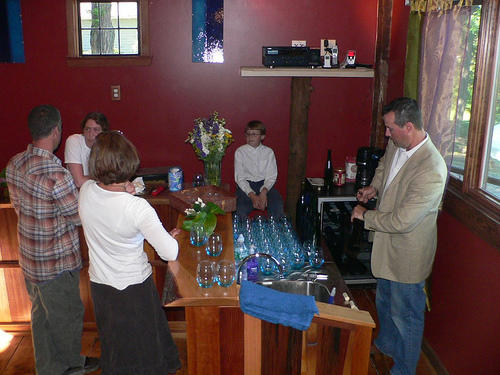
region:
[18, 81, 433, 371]
five people in red room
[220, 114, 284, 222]
boy sitting against wolf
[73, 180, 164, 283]
white shirt of woman standing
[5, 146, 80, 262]
plaid shirt of man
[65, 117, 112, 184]
white short sleeve shirt of woman behind bar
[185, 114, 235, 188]
vase of purple and white flowers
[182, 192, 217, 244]
vase of flowers on bar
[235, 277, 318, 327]
blue cloth on bar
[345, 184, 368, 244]
bottle in man's hand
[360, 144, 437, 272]
tan suit coat of man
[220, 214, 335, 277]
a lot of glasses on the bar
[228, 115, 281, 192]
boy with a white shirt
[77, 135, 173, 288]
woman with a white shirt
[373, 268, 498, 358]
man with blue pants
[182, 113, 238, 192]
flowers at the end of the table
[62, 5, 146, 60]
window with a tree out side of it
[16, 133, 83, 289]
man with a plaid shirt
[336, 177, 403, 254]
man opening a brown bottle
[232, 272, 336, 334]
blue towel on the arm rest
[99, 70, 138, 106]
electrical outlet on the wall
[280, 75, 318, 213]
a long wooden pole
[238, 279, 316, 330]
a dark blue towel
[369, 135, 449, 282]
a man's brown blazer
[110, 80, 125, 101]
a wall outlet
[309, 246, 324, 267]
a blue glass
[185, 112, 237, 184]
a vase of flowers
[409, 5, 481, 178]
part of a large window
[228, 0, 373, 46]
a maroon wall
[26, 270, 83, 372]
a man's black jean pants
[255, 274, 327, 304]
part of a small sink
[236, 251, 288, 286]
A silver sink faucet.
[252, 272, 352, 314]
A small silver sink.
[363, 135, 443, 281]
A beige blazer.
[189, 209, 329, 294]
Small glass cups.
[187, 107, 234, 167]
Purple, yellow, and white flowers.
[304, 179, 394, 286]
A small refrigerator with a glass door.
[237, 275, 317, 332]
A blue dishtowel.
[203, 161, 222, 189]
A glass flower vase.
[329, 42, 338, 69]
A silver cordless phone.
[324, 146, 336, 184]
A tall black bottle.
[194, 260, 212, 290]
a clear blue glass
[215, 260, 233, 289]
a clear blue glass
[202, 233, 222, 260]
a clear blue glass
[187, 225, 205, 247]
a clear blue glass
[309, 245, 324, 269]
a clear blue glass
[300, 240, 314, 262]
a clear blue glass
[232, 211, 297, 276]
a group of clear blue glasses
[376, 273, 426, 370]
a pair of blue jeans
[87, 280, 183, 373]
a long black skirt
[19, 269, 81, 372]
a pair of grey jeans